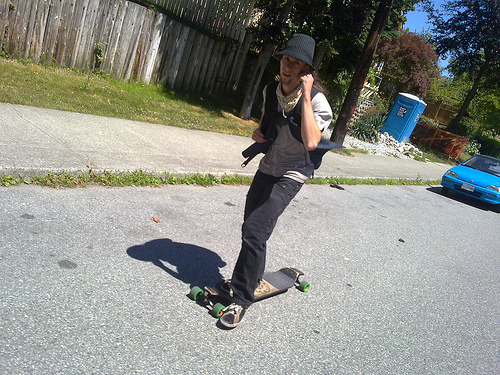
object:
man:
[213, 30, 338, 333]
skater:
[216, 32, 337, 330]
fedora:
[271, 33, 317, 71]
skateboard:
[188, 266, 312, 318]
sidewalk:
[0, 98, 449, 182]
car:
[440, 154, 500, 209]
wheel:
[298, 280, 312, 293]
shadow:
[125, 237, 227, 289]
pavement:
[0, 186, 497, 375]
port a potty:
[378, 91, 428, 144]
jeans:
[231, 169, 303, 309]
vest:
[258, 80, 334, 178]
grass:
[0, 59, 254, 138]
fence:
[0, 0, 257, 99]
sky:
[403, 0, 478, 79]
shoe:
[219, 303, 249, 328]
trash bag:
[379, 92, 428, 143]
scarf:
[276, 81, 304, 113]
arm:
[299, 73, 322, 152]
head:
[279, 33, 316, 85]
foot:
[219, 301, 249, 329]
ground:
[0, 187, 500, 375]